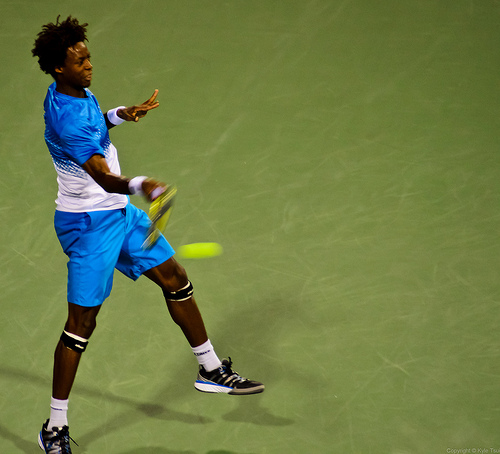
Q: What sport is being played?
A: Tennis.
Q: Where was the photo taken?
A: Court.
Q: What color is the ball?
A: Yellow.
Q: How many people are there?
A: One.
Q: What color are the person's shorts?
A: Blue.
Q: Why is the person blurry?
A: In motion.